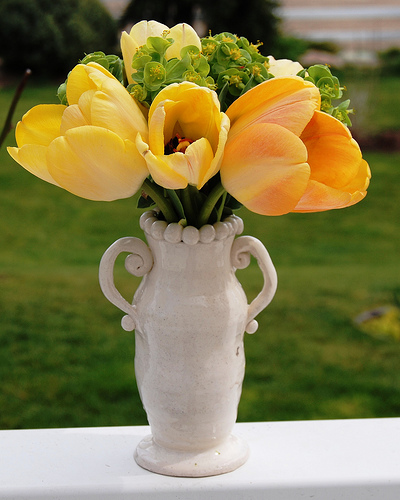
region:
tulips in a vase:
[14, 20, 370, 491]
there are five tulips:
[15, 10, 369, 291]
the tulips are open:
[11, 65, 371, 253]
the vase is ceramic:
[84, 181, 332, 358]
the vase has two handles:
[105, 219, 281, 349]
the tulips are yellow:
[26, 44, 353, 265]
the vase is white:
[59, 221, 313, 491]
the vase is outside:
[83, 196, 328, 466]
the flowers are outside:
[27, 11, 379, 382]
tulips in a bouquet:
[31, 17, 360, 482]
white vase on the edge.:
[92, 209, 277, 477]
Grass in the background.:
[0, 68, 396, 432]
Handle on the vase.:
[228, 228, 280, 336]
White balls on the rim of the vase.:
[136, 208, 244, 248]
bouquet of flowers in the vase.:
[4, 15, 373, 228]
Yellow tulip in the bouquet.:
[222, 71, 374, 218]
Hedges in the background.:
[1, 0, 344, 86]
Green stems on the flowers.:
[137, 169, 240, 226]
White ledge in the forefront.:
[0, 417, 399, 499]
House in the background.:
[270, 0, 398, 71]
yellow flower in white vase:
[23, 97, 137, 201]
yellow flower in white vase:
[134, 80, 235, 193]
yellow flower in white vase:
[230, 89, 352, 200]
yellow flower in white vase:
[118, 14, 202, 88]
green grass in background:
[286, 333, 362, 384]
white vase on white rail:
[97, 224, 279, 447]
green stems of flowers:
[139, 197, 216, 217]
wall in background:
[301, 11, 392, 71]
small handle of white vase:
[87, 239, 151, 323]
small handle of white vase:
[231, 224, 301, 334]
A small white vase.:
[89, 222, 293, 487]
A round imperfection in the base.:
[211, 448, 223, 461]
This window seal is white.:
[284, 432, 378, 481]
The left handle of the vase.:
[85, 227, 162, 345]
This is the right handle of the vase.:
[224, 231, 281, 349]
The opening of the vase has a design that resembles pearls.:
[135, 207, 270, 248]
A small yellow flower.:
[140, 84, 234, 192]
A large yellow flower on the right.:
[230, 76, 379, 221]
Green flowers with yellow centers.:
[126, 36, 278, 97]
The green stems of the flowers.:
[138, 186, 239, 217]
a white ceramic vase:
[96, 212, 276, 476]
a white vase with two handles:
[100, 212, 276, 476]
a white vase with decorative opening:
[97, 208, 277, 476]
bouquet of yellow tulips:
[6, 18, 372, 222]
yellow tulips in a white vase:
[5, 18, 374, 476]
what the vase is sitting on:
[0, 420, 398, 498]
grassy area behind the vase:
[2, 79, 398, 427]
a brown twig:
[0, 65, 33, 146]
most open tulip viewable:
[135, 81, 227, 190]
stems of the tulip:
[144, 185, 233, 219]